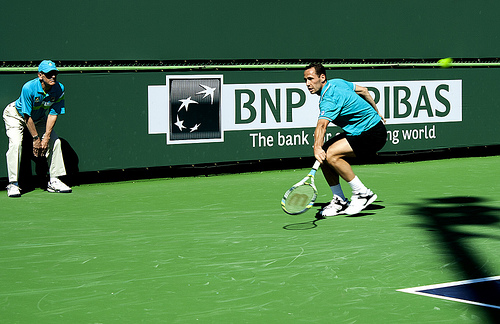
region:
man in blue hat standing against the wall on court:
[3, 53, 73, 205]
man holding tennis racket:
[276, 57, 396, 230]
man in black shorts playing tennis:
[272, 60, 409, 240]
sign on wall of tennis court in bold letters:
[132, 70, 476, 148]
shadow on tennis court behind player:
[391, 183, 498, 320]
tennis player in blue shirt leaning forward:
[273, 57, 405, 227]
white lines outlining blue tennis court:
[391, 271, 499, 311]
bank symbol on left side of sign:
[159, 69, 226, 154]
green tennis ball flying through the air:
[426, 46, 458, 74]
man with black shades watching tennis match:
[1, 56, 95, 200]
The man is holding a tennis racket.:
[274, 44, 391, 236]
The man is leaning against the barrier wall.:
[1, 52, 81, 209]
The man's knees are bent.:
[278, 58, 393, 231]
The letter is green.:
[233, 84, 259, 128]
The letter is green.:
[254, 83, 285, 130]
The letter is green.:
[283, 85, 306, 125]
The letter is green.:
[391, 83, 414, 121]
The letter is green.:
[413, 79, 435, 122]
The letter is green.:
[431, 78, 458, 120]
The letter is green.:
[381, 81, 393, 123]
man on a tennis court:
[278, 50, 399, 261]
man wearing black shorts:
[321, 123, 401, 159]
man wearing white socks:
[347, 168, 372, 198]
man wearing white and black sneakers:
[322, 175, 384, 223]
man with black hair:
[296, 51, 332, 99]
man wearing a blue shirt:
[307, 72, 385, 142]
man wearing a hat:
[31, 60, 71, 83]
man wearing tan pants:
[3, 98, 67, 183]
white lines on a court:
[386, 255, 498, 320]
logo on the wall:
[150, 67, 238, 150]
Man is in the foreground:
[265, 56, 407, 226]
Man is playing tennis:
[263, 61, 403, 228]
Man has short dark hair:
[296, 59, 335, 97]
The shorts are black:
[335, 115, 398, 165]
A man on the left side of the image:
[2, 49, 89, 204]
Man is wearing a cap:
[30, 52, 73, 99]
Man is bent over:
[2, 45, 82, 200]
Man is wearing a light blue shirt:
[308, 79, 390, 141]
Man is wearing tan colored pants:
[0, 99, 74, 184]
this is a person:
[286, 49, 396, 252]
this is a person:
[0, 49, 77, 210]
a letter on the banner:
[228, 81, 260, 133]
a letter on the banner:
[260, 81, 282, 119]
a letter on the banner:
[282, 79, 305, 122]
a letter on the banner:
[376, 85, 390, 125]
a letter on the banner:
[395, 79, 412, 116]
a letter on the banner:
[409, 85, 435, 117]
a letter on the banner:
[436, 75, 465, 115]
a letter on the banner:
[245, 127, 273, 148]